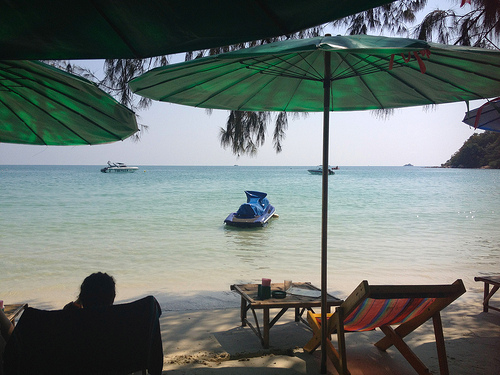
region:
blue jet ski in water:
[214, 173, 279, 237]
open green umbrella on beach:
[148, 25, 495, 129]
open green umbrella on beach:
[17, 52, 137, 163]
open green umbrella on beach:
[21, 0, 382, 41]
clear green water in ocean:
[364, 185, 412, 230]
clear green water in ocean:
[50, 223, 117, 237]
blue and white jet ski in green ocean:
[215, 185, 269, 239]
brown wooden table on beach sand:
[221, 261, 326, 333]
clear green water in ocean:
[362, 211, 423, 243]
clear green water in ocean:
[419, 185, 463, 211]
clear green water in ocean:
[147, 214, 169, 229]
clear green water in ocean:
[255, 236, 295, 246]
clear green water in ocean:
[65, 201, 110, 228]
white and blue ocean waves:
[107, 186, 153, 216]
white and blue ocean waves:
[374, 204, 421, 244]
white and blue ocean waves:
[428, 190, 475, 235]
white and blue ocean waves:
[13, 190, 53, 219]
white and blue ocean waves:
[65, 207, 115, 244]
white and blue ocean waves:
[122, 190, 169, 220]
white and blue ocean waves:
[158, 239, 196, 272]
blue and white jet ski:
[220, 184, 271, 247]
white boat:
[88, 151, 143, 187]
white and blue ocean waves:
[396, 231, 433, 253]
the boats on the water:
[1, 165, 499, 312]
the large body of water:
[1, 165, 498, 313]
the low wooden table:
[229, 280, 344, 350]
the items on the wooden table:
[228, 280, 341, 352]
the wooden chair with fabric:
[303, 276, 465, 373]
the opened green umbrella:
[129, 32, 499, 372]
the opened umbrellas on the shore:
[0, 32, 499, 372]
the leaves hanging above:
[32, 0, 499, 161]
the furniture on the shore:
[3, 263, 499, 373]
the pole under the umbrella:
[128, 32, 496, 373]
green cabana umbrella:
[130, 34, 499, 115]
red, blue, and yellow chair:
[307, 280, 472, 374]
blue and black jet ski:
[220, 186, 277, 231]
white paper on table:
[286, 285, 323, 300]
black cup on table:
[257, 278, 274, 304]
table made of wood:
[227, 278, 345, 349]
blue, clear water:
[1, 165, 498, 282]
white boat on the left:
[100, 160, 138, 173]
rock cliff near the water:
[441, 133, 498, 169]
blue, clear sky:
[0, 59, 498, 165]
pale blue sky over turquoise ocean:
[5, 9, 495, 293]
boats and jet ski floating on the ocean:
[95, 152, 344, 232]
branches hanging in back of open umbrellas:
[6, 2, 491, 154]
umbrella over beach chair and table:
[131, 35, 491, 368]